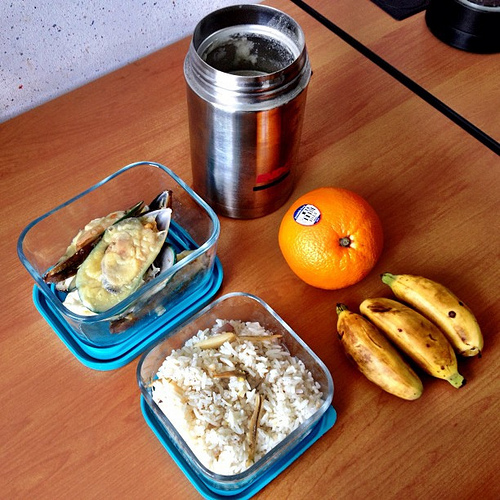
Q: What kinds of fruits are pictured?
A: Bananas and oranges.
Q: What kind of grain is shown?
A: Rice.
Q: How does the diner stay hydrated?
A: By drinking the liquid in the silver cup.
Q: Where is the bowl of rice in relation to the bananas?
A: To the left.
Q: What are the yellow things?
A: Bananas.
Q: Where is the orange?
A: By the bananas.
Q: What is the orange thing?
A: An orange.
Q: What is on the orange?
A: A sticker.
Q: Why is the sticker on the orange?
A: To label it.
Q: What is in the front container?
A: Rice.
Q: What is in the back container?
A: Oysters.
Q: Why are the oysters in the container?
A: To eat.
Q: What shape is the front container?
A: Square.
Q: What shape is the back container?
A: Rectangular.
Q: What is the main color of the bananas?
A: Yellow.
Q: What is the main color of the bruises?
A: Brown.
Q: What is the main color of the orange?
A: Orange.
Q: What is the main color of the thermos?
A: Gray.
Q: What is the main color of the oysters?
A: White.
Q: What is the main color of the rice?
A: White.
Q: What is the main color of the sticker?
A: White.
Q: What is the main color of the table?
A: Brown.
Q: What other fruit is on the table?
A: Bananas.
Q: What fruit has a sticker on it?
A: An orange.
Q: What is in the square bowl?
A: Rice.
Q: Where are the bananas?
A: In front of the orange.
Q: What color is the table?
A: Brown.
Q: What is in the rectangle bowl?
A: Clams.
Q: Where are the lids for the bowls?
A: Under their bowl.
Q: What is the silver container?
A: Thermos.